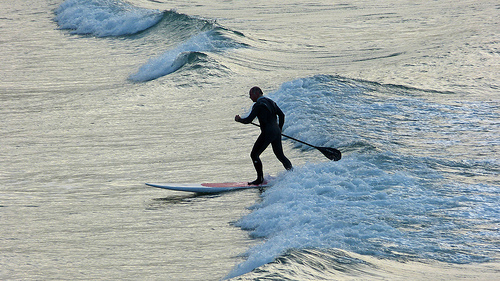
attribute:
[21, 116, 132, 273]
water — calm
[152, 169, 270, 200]
board — red, white, surf